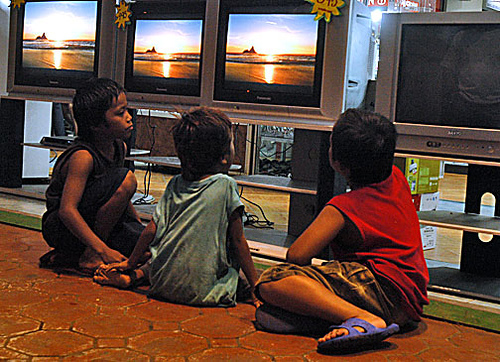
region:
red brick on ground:
[3, 324, 95, 357]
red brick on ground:
[71, 309, 153, 339]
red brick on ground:
[127, 325, 210, 359]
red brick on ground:
[210, 335, 240, 346]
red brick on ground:
[188, 343, 274, 360]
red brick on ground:
[273, 351, 311, 360]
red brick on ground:
[243, 330, 316, 352]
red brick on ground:
[305, 348, 393, 358]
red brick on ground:
[417, 343, 450, 358]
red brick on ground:
[3, 235, 25, 251]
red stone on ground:
[452, 327, 497, 359]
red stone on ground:
[416, 340, 496, 360]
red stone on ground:
[403, 315, 455, 344]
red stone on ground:
[378, 333, 425, 354]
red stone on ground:
[305, 347, 378, 359]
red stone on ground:
[191, 344, 273, 359]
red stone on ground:
[236, 330, 318, 354]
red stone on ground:
[184, 313, 253, 333]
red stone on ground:
[127, 330, 209, 352]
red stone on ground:
[7, 328, 95, 353]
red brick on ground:
[447, 330, 496, 355]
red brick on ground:
[183, 312, 254, 332]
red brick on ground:
[131, 333, 203, 351]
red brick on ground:
[76, 345, 150, 360]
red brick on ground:
[22, 293, 97, 328]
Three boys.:
[36, 78, 440, 345]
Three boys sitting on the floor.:
[27, 73, 432, 345]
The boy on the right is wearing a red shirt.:
[254, 103, 427, 357]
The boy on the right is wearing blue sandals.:
[236, 99, 436, 349]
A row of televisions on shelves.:
[8, 2, 498, 169]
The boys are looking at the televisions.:
[17, 8, 457, 349]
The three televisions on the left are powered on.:
[4, 0, 361, 137]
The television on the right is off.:
[376, 8, 497, 172]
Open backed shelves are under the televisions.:
[6, 95, 498, 322]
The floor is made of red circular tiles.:
[2, 221, 495, 359]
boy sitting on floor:
[314, 108, 438, 358]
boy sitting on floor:
[180, 96, 246, 315]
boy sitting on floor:
[47, 70, 125, 305]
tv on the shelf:
[372, 11, 498, 111]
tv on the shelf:
[227, 14, 337, 119]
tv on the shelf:
[92, 5, 219, 93]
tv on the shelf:
[21, 6, 88, 78]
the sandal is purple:
[330, 316, 388, 341]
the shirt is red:
[354, 212, 406, 254]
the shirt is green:
[147, 209, 225, 262]